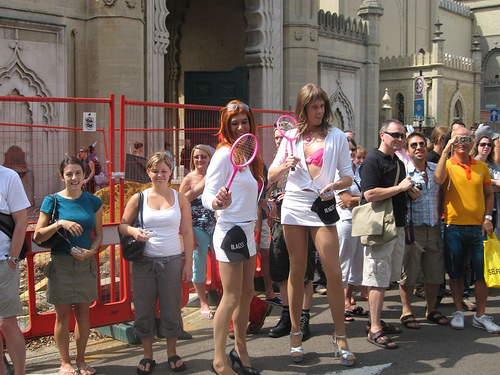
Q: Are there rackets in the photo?
A: Yes, there is a racket.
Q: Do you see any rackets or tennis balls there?
A: Yes, there is a racket.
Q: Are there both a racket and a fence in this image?
A: Yes, there are both a racket and a fence.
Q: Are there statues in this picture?
A: No, there are no statues.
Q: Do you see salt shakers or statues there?
A: No, there are no statues or salt shakers.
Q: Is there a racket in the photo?
A: Yes, there is a racket.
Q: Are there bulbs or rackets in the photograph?
A: Yes, there is a racket.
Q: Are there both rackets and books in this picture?
A: No, there is a racket but no books.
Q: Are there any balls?
A: No, there are no balls.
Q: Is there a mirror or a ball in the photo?
A: No, there are no balls or mirrors.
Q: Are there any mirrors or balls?
A: No, there are no balls or mirrors.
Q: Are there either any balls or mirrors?
A: No, there are no balls or mirrors.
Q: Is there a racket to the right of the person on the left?
A: Yes, there is a racket to the right of the person.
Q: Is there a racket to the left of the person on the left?
A: No, the racket is to the right of the person.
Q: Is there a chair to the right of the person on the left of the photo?
A: No, there is a racket to the right of the person.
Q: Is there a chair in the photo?
A: No, there are no chairs.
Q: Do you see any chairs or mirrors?
A: No, there are no chairs or mirrors.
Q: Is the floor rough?
A: Yes, the floor is rough.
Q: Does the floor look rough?
A: Yes, the floor is rough.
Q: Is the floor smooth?
A: No, the floor is rough.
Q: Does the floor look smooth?
A: No, the floor is rough.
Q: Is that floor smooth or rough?
A: The floor is rough.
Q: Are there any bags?
A: Yes, there is a bag.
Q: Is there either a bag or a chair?
A: Yes, there is a bag.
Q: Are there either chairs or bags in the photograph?
A: Yes, there is a bag.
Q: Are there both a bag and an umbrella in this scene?
A: No, there is a bag but no umbrellas.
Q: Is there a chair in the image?
A: No, there are no chairs.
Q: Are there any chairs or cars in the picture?
A: No, there are no chairs or cars.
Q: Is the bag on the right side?
A: Yes, the bag is on the right of the image.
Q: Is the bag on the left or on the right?
A: The bag is on the right of the image.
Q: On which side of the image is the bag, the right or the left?
A: The bag is on the right of the image.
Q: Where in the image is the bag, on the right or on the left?
A: The bag is on the right of the image.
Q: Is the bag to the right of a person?
A: Yes, the bag is to the right of a person.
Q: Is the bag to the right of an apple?
A: No, the bag is to the right of a person.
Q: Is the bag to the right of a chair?
A: No, the bag is to the right of a person.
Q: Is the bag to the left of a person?
A: No, the bag is to the right of a person.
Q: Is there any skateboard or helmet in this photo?
A: No, there are no helmets or skateboards.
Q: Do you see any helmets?
A: No, there are no helmets.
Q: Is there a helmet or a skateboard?
A: No, there are no helmets or skateboards.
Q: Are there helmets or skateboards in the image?
A: No, there are no helmets or skateboards.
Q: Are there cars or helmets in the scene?
A: No, there are no cars or helmets.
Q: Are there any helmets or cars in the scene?
A: No, there are no cars or helmets.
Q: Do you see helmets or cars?
A: No, there are no cars or helmets.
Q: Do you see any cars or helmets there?
A: No, there are no cars or helmets.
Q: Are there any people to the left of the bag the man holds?
A: Yes, there is a person to the left of the bag.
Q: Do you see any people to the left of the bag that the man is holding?
A: Yes, there is a person to the left of the bag.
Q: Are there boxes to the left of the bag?
A: No, there is a person to the left of the bag.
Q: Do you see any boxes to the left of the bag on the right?
A: No, there is a person to the left of the bag.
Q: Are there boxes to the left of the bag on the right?
A: No, there is a person to the left of the bag.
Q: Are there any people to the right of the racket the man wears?
A: Yes, there is a person to the right of the racket.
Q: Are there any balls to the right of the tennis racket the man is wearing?
A: No, there is a person to the right of the racket.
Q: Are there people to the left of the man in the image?
A: Yes, there is a person to the left of the man.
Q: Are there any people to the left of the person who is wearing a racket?
A: Yes, there is a person to the left of the man.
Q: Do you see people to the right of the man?
A: No, the person is to the left of the man.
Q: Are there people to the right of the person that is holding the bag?
A: No, the person is to the left of the man.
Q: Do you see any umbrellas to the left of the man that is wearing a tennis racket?
A: No, there is a person to the left of the man.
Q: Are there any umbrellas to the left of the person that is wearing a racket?
A: No, there is a person to the left of the man.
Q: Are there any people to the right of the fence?
A: Yes, there is a person to the right of the fence.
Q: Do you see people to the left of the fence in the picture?
A: No, the person is to the right of the fence.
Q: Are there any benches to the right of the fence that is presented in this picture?
A: No, there is a person to the right of the fence.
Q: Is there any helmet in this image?
A: No, there are no helmets.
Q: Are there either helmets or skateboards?
A: No, there are no helmets or skateboards.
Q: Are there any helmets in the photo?
A: No, there are no helmets.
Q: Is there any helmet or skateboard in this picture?
A: No, there are no helmets or skateboards.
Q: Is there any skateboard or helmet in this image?
A: No, there are no helmets or skateboards.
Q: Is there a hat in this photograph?
A: Yes, there is a hat.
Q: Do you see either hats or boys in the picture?
A: Yes, there is a hat.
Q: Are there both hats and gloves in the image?
A: No, there is a hat but no gloves.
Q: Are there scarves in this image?
A: No, there are no scarves.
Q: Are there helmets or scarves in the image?
A: No, there are no scarves or helmets.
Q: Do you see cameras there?
A: Yes, there is a camera.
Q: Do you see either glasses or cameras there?
A: Yes, there is a camera.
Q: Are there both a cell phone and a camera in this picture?
A: No, there is a camera but no cell phones.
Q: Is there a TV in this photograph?
A: No, there are no televisions.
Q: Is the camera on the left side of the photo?
A: Yes, the camera is on the left of the image.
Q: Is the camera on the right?
A: No, the camera is on the left of the image.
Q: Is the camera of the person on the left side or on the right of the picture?
A: The camera is on the left of the image.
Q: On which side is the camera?
A: The camera is on the left of the image.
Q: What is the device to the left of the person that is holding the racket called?
A: The device is a camera.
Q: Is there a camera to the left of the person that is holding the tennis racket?
A: Yes, there is a camera to the left of the person.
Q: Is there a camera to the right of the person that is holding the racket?
A: No, the camera is to the left of the person.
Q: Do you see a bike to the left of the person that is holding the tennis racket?
A: No, there is a camera to the left of the person.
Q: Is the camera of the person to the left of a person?
A: Yes, the camera is to the left of a person.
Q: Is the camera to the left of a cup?
A: No, the camera is to the left of a person.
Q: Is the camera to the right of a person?
A: No, the camera is to the left of a person.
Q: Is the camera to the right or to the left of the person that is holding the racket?
A: The camera is to the left of the person.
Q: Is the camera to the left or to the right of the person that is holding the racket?
A: The camera is to the left of the person.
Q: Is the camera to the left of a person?
A: Yes, the camera is to the left of a person.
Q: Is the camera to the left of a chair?
A: No, the camera is to the left of a person.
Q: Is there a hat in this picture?
A: Yes, there is a hat.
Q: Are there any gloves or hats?
A: Yes, there is a hat.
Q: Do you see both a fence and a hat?
A: Yes, there are both a hat and a fence.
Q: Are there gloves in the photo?
A: No, there are no gloves.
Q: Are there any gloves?
A: No, there are no gloves.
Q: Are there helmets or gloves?
A: No, there are no gloves or helmets.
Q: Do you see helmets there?
A: No, there are no helmets.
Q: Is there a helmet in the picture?
A: No, there are no helmets.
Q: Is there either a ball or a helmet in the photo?
A: No, there are no helmets or balls.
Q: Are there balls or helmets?
A: No, there are no helmets or balls.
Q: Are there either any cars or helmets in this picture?
A: No, there are no cars or helmets.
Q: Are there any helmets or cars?
A: No, there are no cars or helmets.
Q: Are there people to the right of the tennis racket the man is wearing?
A: Yes, there is a person to the right of the tennis racket.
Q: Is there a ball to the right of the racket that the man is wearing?
A: No, there is a person to the right of the racket.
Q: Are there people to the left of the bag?
A: Yes, there is a person to the left of the bag.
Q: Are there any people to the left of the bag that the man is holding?
A: Yes, there is a person to the left of the bag.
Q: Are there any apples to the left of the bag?
A: No, there is a person to the left of the bag.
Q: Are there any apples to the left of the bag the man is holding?
A: No, there is a person to the left of the bag.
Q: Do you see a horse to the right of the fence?
A: No, there is a person to the right of the fence.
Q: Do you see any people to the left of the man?
A: Yes, there is a person to the left of the man.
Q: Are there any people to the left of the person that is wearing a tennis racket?
A: Yes, there is a person to the left of the man.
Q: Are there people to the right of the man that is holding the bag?
A: No, the person is to the left of the man.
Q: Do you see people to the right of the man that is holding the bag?
A: No, the person is to the left of the man.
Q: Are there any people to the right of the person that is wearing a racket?
A: No, the person is to the left of the man.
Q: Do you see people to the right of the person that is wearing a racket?
A: No, the person is to the left of the man.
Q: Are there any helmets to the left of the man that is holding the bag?
A: No, there is a person to the left of the man.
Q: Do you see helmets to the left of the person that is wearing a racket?
A: No, there is a person to the left of the man.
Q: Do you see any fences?
A: Yes, there is a fence.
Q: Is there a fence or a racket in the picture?
A: Yes, there is a fence.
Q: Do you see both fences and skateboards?
A: No, there is a fence but no skateboards.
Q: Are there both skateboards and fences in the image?
A: No, there is a fence but no skateboards.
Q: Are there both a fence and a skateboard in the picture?
A: No, there is a fence but no skateboards.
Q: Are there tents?
A: No, there are no tents.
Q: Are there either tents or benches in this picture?
A: No, there are no tents or benches.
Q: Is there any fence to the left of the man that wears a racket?
A: Yes, there is a fence to the left of the man.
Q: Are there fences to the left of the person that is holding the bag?
A: Yes, there is a fence to the left of the man.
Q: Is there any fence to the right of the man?
A: No, the fence is to the left of the man.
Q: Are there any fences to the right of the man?
A: No, the fence is to the left of the man.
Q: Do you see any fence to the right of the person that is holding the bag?
A: No, the fence is to the left of the man.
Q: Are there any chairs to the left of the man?
A: No, there is a fence to the left of the man.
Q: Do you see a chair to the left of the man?
A: No, there is a fence to the left of the man.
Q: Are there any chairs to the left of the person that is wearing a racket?
A: No, there is a fence to the left of the man.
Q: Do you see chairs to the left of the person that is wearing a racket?
A: No, there is a fence to the left of the man.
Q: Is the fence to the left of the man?
A: Yes, the fence is to the left of the man.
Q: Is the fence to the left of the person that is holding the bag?
A: Yes, the fence is to the left of the man.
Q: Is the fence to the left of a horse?
A: No, the fence is to the left of the man.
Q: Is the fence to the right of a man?
A: No, the fence is to the left of a man.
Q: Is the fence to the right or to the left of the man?
A: The fence is to the left of the man.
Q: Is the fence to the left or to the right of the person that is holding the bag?
A: The fence is to the left of the man.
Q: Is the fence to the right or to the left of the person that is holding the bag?
A: The fence is to the left of the man.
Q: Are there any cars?
A: No, there are no cars.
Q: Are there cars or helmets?
A: No, there are no cars or helmets.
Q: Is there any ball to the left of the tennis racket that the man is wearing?
A: No, there is a person to the left of the tennis racket.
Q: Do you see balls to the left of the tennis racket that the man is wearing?
A: No, there is a person to the left of the tennis racket.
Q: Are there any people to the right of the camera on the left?
A: Yes, there is a person to the right of the camera.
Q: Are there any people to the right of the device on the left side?
A: Yes, there is a person to the right of the camera.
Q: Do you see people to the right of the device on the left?
A: Yes, there is a person to the right of the camera.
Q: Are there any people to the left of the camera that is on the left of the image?
A: No, the person is to the right of the camera.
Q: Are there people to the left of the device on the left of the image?
A: No, the person is to the right of the camera.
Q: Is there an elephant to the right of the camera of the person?
A: No, there is a person to the right of the camera.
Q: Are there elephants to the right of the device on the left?
A: No, there is a person to the right of the camera.